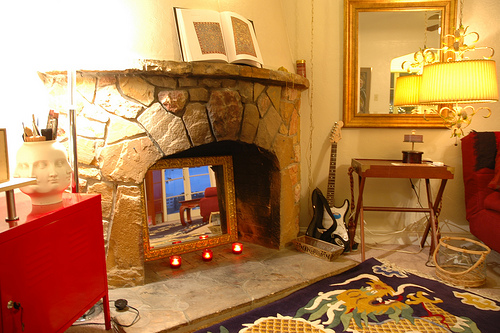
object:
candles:
[170, 242, 243, 269]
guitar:
[305, 121, 351, 255]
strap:
[304, 186, 339, 246]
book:
[170, 6, 262, 64]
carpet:
[193, 258, 498, 332]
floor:
[134, 232, 500, 332]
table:
[0, 180, 105, 332]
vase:
[11, 137, 76, 206]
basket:
[432, 236, 491, 288]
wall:
[300, 0, 499, 232]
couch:
[461, 129, 500, 255]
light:
[392, 27, 499, 146]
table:
[347, 156, 454, 262]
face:
[18, 146, 73, 195]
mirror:
[145, 166, 226, 251]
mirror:
[351, 4, 441, 117]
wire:
[365, 212, 430, 259]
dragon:
[237, 274, 466, 332]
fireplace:
[137, 119, 286, 259]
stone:
[71, 72, 310, 169]